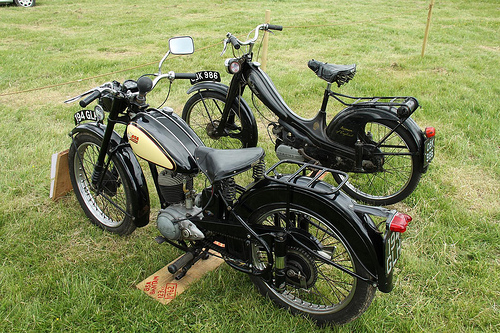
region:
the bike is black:
[158, 19, 488, 241]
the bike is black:
[200, 33, 403, 213]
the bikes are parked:
[46, 38, 418, 328]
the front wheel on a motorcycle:
[55, 118, 175, 223]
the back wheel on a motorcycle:
[201, 191, 386, 311]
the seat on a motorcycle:
[155, 100, 290, 230]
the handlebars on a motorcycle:
[70, 50, 222, 125]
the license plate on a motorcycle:
[360, 211, 440, 283]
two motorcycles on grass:
[55, 30, 423, 261]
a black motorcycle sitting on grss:
[28, 94, 436, 276]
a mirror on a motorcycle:
[157, 10, 228, 76]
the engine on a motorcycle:
[136, 191, 238, 273]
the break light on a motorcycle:
[359, 189, 486, 247]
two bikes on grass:
[35, 40, 475, 311]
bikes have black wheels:
[211, 188, 409, 315]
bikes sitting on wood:
[130, 241, 235, 296]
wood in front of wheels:
[55, 134, 100, 216]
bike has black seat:
[190, 125, 287, 246]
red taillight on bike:
[398, 195, 428, 250]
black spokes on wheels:
[71, 150, 176, 244]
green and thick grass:
[30, 11, 108, 85]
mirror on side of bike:
[177, 24, 231, 79]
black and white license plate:
[341, 213, 399, 288]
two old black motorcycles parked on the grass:
[11, 28, 441, 330]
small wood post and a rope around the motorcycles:
[14, 13, 441, 159]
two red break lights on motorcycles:
[374, 119, 450, 243]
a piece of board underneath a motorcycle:
[145, 223, 216, 310]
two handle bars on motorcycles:
[65, 18, 285, 144]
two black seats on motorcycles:
[180, 45, 357, 212]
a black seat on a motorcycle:
[187, 138, 264, 190]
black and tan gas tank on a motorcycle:
[121, 113, 196, 180]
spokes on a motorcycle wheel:
[289, 219, 357, 314]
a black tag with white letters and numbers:
[188, 57, 222, 86]